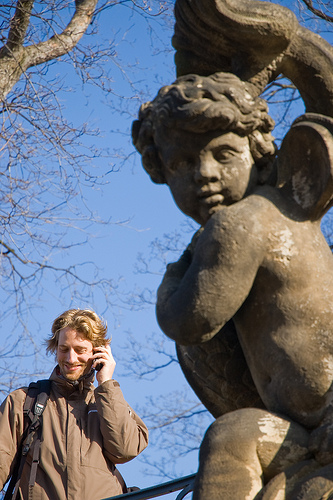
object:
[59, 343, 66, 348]
eyebrows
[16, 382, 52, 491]
strap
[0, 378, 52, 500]
bag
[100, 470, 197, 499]
rail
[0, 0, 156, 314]
leafless tree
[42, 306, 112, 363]
blonde hair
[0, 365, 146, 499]
coat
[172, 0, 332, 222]
wings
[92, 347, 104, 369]
phone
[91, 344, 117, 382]
hand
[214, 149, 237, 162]
eye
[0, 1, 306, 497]
sky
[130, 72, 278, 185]
hair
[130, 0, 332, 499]
carving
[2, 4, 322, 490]
park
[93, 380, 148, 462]
sleeves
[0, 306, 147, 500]
man